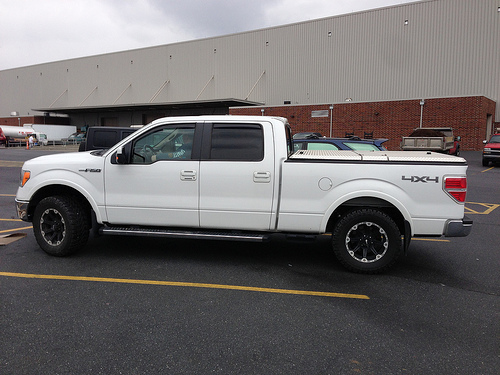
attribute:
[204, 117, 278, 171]
window — dark tinted, truck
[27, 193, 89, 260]
tire — truck's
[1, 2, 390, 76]
sky — cloudy, grey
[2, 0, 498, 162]
building — tall, grey, brown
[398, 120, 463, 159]
truck — red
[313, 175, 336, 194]
compartment — round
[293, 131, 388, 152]
car — blue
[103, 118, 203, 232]
door — white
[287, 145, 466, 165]
bed cover — metal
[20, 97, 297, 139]
awning — large, metal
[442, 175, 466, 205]
light — red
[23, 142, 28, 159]
cone — orange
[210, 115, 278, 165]
window — tinted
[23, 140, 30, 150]
traffic cone — orange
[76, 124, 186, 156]
car — black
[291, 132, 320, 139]
car — black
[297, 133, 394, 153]
car — blue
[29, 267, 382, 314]
line — yellow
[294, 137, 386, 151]
station wagon — blue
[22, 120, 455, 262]
truck — red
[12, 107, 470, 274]
truck — white, large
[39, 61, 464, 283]
truck — white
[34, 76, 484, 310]
truck — white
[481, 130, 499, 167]
truck — large, red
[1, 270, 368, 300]
line — yellow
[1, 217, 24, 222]
line — yellow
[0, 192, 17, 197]
line — yellow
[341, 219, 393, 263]
rim — white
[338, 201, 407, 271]
wheel — large, truck, black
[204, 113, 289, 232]
cab — extended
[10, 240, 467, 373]
road — asphalt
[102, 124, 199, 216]
door — white, car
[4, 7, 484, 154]
building — industrial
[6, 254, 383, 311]
line — yellow